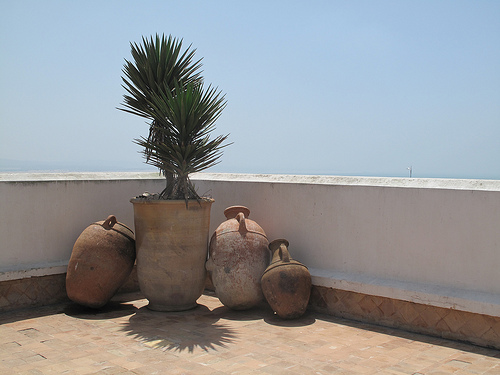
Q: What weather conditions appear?
A: It is cloudless.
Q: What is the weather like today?
A: It is cloudless.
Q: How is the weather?
A: It is cloudless.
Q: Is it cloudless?
A: Yes, it is cloudless.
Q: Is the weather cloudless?
A: Yes, it is cloudless.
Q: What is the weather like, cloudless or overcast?
A: It is cloudless.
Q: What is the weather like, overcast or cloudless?
A: It is cloudless.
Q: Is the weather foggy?
A: No, it is cloudless.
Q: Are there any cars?
A: No, there are no cars.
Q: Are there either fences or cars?
A: No, there are no cars or fences.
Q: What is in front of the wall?
A: The plant pot is in front of the wall.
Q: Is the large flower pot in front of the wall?
A: Yes, the flower pot is in front of the wall.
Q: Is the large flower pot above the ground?
A: Yes, the plant pot is above the ground.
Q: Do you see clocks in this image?
A: No, there are no clocks.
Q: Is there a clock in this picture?
A: No, there are no clocks.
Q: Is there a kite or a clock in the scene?
A: No, there are no clocks or kites.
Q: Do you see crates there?
A: No, there are no crates.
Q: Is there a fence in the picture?
A: No, there are no fences.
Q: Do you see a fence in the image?
A: No, there are no fences.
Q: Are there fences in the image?
A: No, there are no fences.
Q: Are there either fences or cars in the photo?
A: No, there are no fences or cars.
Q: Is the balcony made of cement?
A: Yes, the balcony is made of cement.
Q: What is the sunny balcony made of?
A: The balcony is made of concrete.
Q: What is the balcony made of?
A: The balcony is made of concrete.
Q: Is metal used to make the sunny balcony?
A: No, the balcony is made of concrete.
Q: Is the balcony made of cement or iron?
A: The balcony is made of cement.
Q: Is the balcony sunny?
A: Yes, the balcony is sunny.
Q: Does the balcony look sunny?
A: Yes, the balcony is sunny.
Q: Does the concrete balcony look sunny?
A: Yes, the balcony is sunny.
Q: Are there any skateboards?
A: No, there are no skateboards.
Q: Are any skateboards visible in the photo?
A: No, there are no skateboards.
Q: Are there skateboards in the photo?
A: No, there are no skateboards.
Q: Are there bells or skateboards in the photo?
A: No, there are no skateboards or bells.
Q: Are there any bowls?
A: No, there are no bowls.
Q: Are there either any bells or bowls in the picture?
A: No, there are no bowls or bells.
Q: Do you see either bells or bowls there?
A: No, there are no bowls or bells.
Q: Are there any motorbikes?
A: No, there are no motorbikes.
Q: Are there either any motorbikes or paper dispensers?
A: No, there are no motorbikes or paper dispensers.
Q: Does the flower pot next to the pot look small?
A: Yes, the flower pot is small.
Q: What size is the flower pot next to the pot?
A: The flower pot is small.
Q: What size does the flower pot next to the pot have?
A: The flower pot has small size.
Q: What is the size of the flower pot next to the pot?
A: The flower pot is small.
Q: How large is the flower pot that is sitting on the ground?
A: The flower pot is small.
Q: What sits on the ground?
A: The flower pot sits on the ground.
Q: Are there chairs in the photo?
A: No, there are no chairs.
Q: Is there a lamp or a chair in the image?
A: No, there are no chairs or lamps.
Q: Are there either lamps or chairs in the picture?
A: No, there are no chairs or lamps.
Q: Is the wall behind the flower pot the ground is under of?
A: Yes, the wall is behind the flower pot.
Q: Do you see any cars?
A: No, there are no cars.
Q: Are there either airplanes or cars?
A: No, there are no cars or airplanes.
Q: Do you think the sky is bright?
A: Yes, the sky is bright.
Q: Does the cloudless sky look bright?
A: Yes, the sky is bright.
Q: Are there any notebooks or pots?
A: Yes, there is a pot.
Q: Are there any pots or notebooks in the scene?
A: Yes, there is a pot.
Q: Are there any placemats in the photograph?
A: No, there are no placemats.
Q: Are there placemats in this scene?
A: No, there are no placemats.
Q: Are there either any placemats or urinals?
A: No, there are no placemats or urinals.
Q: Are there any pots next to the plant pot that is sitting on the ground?
A: Yes, there is a pot next to the flower pot.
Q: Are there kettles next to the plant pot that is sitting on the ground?
A: No, there is a pot next to the plant pot.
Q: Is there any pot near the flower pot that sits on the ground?
A: Yes, there is a pot near the plant pot.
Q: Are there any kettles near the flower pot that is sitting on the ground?
A: No, there is a pot near the flower pot.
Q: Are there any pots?
A: Yes, there is a pot.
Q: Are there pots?
A: Yes, there is a pot.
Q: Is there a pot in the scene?
A: Yes, there is a pot.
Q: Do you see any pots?
A: Yes, there is a pot.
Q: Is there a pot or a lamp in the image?
A: Yes, there is a pot.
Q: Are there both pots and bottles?
A: No, there is a pot but no bottles.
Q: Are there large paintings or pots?
A: Yes, there is a large pot.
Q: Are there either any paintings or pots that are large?
A: Yes, the pot is large.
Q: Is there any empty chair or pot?
A: Yes, there is an empty pot.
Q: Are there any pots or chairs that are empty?
A: Yes, the pot is empty.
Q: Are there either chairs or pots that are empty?
A: Yes, the pot is empty.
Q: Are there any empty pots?
A: Yes, there is an empty pot.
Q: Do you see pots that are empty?
A: Yes, there is a pot that is empty.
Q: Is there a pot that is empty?
A: Yes, there is a pot that is empty.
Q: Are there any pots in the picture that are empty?
A: Yes, there is a pot that is empty.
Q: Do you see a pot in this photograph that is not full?
A: Yes, there is a empty pot.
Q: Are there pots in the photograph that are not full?
A: Yes, there is a empty pot.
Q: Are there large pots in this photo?
A: Yes, there is a large pot.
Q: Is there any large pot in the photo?
A: Yes, there is a large pot.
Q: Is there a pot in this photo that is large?
A: Yes, there is a pot that is large.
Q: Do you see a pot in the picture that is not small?
A: Yes, there is a large pot.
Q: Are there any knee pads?
A: No, there are no knee pads.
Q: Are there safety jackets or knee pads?
A: No, there are no knee pads or safety jackets.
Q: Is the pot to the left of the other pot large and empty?
A: Yes, the pot is large and empty.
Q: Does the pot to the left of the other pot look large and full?
A: No, the pot is large but empty.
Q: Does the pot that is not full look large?
A: Yes, the pot is large.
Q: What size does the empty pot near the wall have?
A: The pot has large size.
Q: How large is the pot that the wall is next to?
A: The pot is large.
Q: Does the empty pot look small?
A: No, the pot is large.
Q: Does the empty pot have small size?
A: No, the pot is large.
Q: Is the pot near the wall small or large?
A: The pot is large.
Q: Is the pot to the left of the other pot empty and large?
A: Yes, the pot is empty and large.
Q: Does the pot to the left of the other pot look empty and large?
A: Yes, the pot is empty and large.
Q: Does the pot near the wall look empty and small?
A: No, the pot is empty but large.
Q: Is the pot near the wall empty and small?
A: No, the pot is empty but large.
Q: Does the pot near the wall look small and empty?
A: No, the pot is empty but large.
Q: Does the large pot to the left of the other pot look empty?
A: Yes, the pot is empty.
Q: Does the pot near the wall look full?
A: No, the pot is empty.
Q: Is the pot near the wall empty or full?
A: The pot is empty.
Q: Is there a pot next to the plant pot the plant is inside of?
A: Yes, there is a pot next to the flower pot.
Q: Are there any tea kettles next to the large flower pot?
A: No, there is a pot next to the plant pot.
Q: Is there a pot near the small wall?
A: Yes, there is a pot near the wall.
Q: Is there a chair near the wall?
A: No, there is a pot near the wall.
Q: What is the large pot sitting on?
A: The pot is sitting on the balcony.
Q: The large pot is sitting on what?
A: The pot is sitting on the balcony.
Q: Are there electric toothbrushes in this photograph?
A: No, there are no electric toothbrushes.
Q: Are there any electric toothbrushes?
A: No, there are no electric toothbrushes.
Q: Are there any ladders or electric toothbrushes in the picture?
A: No, there are no electric toothbrushes or ladders.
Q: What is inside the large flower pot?
A: The plant is inside the plant pot.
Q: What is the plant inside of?
A: The plant is inside the flower pot.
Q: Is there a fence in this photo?
A: No, there are no fences.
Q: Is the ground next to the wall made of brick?
A: Yes, the ground is made of brick.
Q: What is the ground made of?
A: The ground is made of brick.